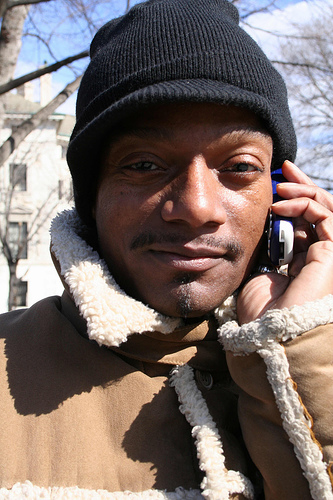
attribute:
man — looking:
[3, 1, 330, 498]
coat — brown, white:
[4, 260, 329, 496]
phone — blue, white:
[267, 165, 294, 265]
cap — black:
[73, 0, 300, 154]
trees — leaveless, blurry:
[273, 2, 333, 162]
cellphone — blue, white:
[262, 167, 287, 274]